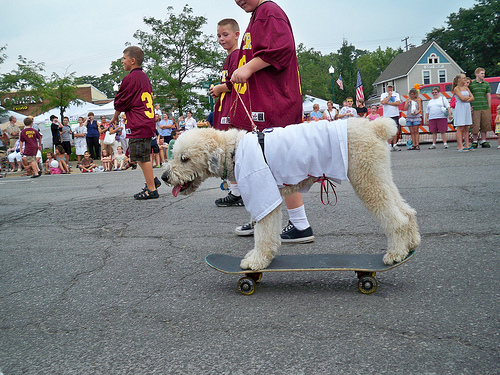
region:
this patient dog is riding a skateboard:
[156, 116, 423, 294]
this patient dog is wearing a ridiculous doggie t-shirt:
[156, 112, 426, 275]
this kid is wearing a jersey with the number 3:
[112, 43, 163, 139]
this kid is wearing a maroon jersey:
[111, 65, 159, 140]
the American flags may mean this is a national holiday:
[329, 67, 369, 112]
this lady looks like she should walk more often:
[423, 83, 453, 145]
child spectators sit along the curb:
[43, 145, 130, 175]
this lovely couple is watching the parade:
[450, 64, 495, 154]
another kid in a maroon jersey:
[18, 115, 47, 177]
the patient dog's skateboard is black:
[198, 243, 421, 295]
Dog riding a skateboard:
[160, 113, 424, 296]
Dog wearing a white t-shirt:
[161, 113, 423, 269]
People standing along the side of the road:
[0, 64, 499, 177]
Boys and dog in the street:
[108, 0, 422, 295]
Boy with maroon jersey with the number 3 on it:
[102, 46, 160, 202]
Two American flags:
[333, 69, 363, 112]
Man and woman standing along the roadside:
[449, 68, 491, 153]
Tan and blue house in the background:
[371, 39, 467, 97]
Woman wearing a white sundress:
[450, 74, 473, 155]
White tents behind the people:
[0, 96, 121, 146]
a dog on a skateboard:
[145, 106, 457, 304]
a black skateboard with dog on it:
[182, 239, 432, 323]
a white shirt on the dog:
[221, 117, 361, 222]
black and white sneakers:
[227, 211, 327, 257]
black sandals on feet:
[123, 178, 161, 206]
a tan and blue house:
[385, 38, 475, 166]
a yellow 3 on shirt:
[143, 85, 155, 125]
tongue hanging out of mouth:
[162, 182, 196, 195]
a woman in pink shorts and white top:
[414, 90, 465, 148]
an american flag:
[345, 64, 376, 114]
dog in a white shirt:
[164, 120, 444, 278]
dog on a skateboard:
[159, 118, 432, 298]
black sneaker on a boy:
[286, 217, 311, 248]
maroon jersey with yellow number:
[117, 64, 169, 145]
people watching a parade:
[11, 106, 124, 196]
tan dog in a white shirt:
[161, 117, 425, 261]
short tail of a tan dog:
[369, 110, 399, 140]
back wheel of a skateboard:
[344, 266, 386, 301]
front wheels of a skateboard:
[237, 271, 265, 296]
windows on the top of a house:
[425, 36, 444, 68]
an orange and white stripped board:
[375, 115, 463, 140]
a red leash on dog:
[220, 62, 285, 182]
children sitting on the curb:
[42, 140, 135, 175]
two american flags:
[332, 67, 380, 108]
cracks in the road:
[25, 172, 206, 338]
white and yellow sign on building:
[7, 91, 63, 116]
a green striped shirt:
[460, 68, 498, 120]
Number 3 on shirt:
[126, 76, 162, 132]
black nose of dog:
[160, 166, 175, 190]